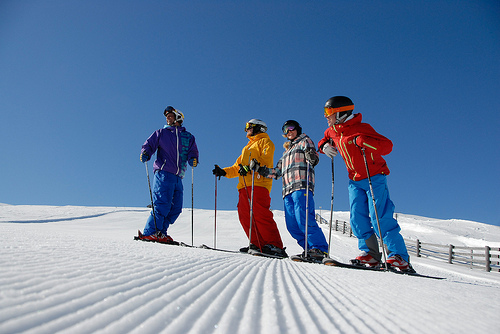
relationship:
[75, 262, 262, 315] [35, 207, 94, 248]
hill has snow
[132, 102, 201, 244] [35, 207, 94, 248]
man on snow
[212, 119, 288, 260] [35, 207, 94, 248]
man on snow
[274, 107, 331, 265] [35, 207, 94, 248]
skier on snow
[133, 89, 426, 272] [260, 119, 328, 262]
group of man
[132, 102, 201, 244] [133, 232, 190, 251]
man wearing skis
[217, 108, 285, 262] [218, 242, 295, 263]
man wearing skis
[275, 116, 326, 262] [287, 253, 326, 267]
man wearing skis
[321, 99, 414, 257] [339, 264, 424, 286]
woman wearing skis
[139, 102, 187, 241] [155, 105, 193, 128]
man wearing a helmet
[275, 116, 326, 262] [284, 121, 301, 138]
man wearing helmet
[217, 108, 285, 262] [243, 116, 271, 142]
man wearing a helmet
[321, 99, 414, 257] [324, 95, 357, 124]
woman wearing a helmet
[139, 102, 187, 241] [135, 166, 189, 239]
man wearing pants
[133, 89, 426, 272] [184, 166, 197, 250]
people are holding ski poles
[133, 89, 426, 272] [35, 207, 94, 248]
people are standing o snow